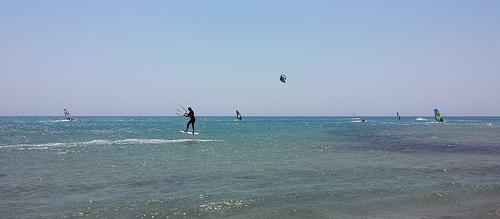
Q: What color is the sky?
A: Light blue.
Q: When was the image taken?
A: During the day.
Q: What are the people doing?
A: Kiteboarding and windsailing.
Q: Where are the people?
A: In the ocean.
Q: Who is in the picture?
A: Kiteboarders and windsailers.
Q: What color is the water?
A: Dark blue.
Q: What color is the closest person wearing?
A: Black.